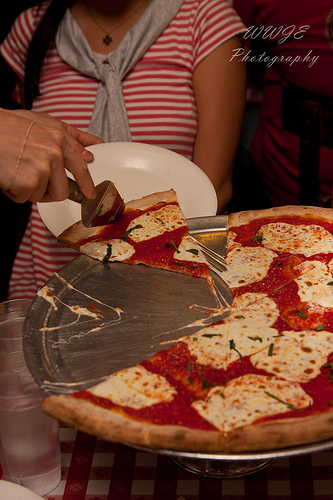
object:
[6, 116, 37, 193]
band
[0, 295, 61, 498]
cup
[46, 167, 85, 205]
handles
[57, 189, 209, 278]
pizza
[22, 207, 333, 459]
silver tray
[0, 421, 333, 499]
table cloth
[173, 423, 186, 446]
spot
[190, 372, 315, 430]
cheese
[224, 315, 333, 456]
pizza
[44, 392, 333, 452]
crust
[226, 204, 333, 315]
pizza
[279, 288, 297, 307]
red sauce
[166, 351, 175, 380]
red sauce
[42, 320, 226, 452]
pizza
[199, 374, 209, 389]
flake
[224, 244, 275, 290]
cheese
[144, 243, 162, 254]
sauce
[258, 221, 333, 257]
cheese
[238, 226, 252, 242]
sauce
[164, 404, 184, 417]
sauce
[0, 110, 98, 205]
hand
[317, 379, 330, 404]
sauce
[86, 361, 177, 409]
cheese